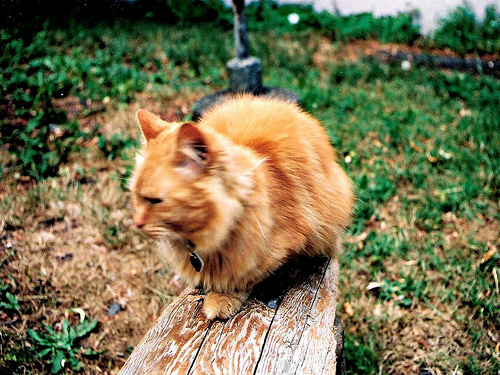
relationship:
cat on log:
[124, 89, 367, 321] [117, 255, 340, 375]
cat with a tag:
[124, 89, 367, 321] [189, 252, 204, 274]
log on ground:
[117, 255, 340, 375] [1, 0, 499, 374]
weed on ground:
[27, 319, 99, 374] [1, 0, 499, 374]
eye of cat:
[144, 196, 163, 205] [124, 89, 367, 321]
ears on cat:
[137, 106, 211, 165] [124, 89, 367, 321]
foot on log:
[203, 290, 239, 319] [117, 255, 340, 375]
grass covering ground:
[0, 19, 499, 374] [1, 0, 499, 374]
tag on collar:
[189, 252, 204, 274] [186, 237, 196, 248]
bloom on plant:
[288, 12, 300, 23] [261, 4, 316, 30]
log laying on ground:
[117, 255, 340, 375] [1, 0, 499, 374]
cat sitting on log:
[124, 89, 367, 321] [117, 255, 340, 375]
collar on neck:
[186, 237, 196, 248] [134, 142, 255, 253]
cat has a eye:
[124, 89, 367, 321] [144, 196, 163, 205]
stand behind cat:
[191, 1, 300, 122] [124, 89, 367, 321]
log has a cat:
[117, 255, 340, 375] [124, 89, 367, 321]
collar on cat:
[186, 237, 196, 248] [124, 89, 367, 321]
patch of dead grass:
[1, 140, 190, 373] [0, 19, 499, 374]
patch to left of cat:
[1, 140, 190, 373] [124, 89, 367, 321]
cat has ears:
[124, 89, 367, 321] [137, 106, 211, 165]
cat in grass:
[124, 89, 367, 321] [0, 19, 499, 374]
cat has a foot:
[124, 89, 367, 321] [203, 290, 239, 319]